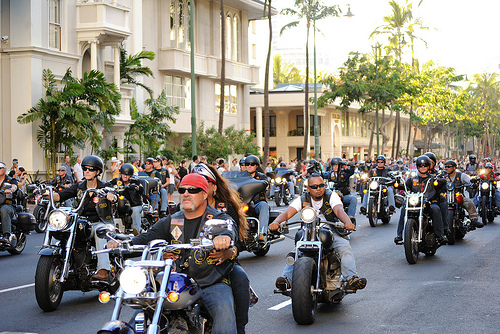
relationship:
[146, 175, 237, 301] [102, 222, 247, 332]
person on motorcycle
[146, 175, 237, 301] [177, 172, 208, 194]
person wearing bandana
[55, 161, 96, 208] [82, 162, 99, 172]
person wearing helmet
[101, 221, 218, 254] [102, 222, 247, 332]
handle bars on motorcycle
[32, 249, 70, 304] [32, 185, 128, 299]
wheel on motorcycle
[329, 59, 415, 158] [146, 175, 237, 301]
tree behind person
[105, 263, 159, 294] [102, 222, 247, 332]
headlight on motorcycle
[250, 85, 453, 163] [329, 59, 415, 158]
building behind tree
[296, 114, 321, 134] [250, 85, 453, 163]
window on building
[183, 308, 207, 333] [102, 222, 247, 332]
gas tank on motorcycle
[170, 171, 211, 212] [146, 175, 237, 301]
head of person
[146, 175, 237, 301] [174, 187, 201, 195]
person wearing sunglasses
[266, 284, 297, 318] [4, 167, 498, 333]
line on road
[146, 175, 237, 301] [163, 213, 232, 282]
person wearing vest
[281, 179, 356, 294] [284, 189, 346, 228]
person wearing shirt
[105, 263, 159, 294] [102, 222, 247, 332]
headlight on front of motorcycle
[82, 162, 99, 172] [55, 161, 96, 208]
helmet on person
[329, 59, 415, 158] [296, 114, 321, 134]
tree next to window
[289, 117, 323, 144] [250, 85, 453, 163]
balcony on building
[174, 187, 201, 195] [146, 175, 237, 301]
sunglasses on person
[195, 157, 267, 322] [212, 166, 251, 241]
person with hair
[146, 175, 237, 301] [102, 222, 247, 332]
person riding motorcycle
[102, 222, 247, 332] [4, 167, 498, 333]
motorcycle on road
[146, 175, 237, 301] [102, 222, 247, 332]
person driving motorcycle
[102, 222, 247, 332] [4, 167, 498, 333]
motorcycle on top of road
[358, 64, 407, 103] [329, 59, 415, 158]
leaves on tree